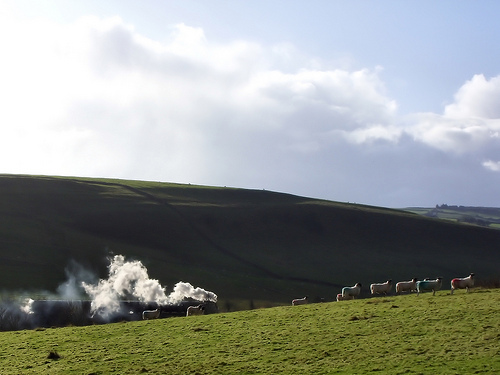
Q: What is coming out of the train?
A: Smoke.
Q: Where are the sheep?
A: Standing in the grass.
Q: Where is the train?
A: On the tracks.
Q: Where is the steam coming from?
A: The train.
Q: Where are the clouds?
A: In the sky.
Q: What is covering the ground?
A: Grass.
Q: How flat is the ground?
A: Sloped.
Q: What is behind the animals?
A: Train.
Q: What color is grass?
A: Green.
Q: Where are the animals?
A: In a field.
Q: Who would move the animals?
A: Herder.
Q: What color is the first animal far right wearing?
A: Red.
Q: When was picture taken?
A: Daytime.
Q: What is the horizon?
A: Hills.